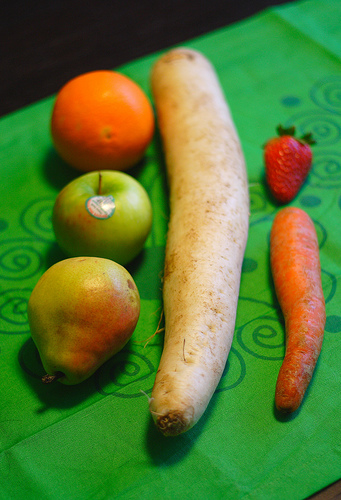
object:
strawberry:
[260, 122, 316, 201]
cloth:
[1, 2, 339, 499]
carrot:
[268, 206, 325, 417]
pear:
[26, 256, 140, 385]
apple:
[52, 168, 151, 264]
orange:
[50, 71, 154, 172]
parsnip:
[148, 47, 249, 437]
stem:
[40, 373, 55, 387]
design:
[0, 73, 340, 399]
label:
[85, 192, 116, 218]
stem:
[260, 120, 316, 145]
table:
[1, 0, 340, 500]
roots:
[155, 408, 183, 438]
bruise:
[124, 278, 140, 304]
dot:
[280, 94, 299, 109]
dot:
[300, 190, 322, 208]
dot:
[323, 314, 340, 333]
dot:
[239, 253, 257, 271]